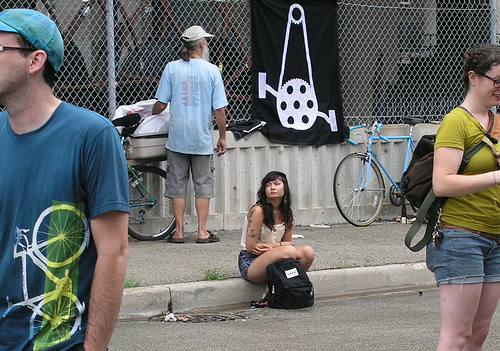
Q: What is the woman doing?
A: Sitting.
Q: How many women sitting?
A: One.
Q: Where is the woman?
A: By the sidewalk.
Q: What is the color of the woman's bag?
A: Black.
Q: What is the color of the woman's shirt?
A: White.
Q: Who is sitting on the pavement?
A: A woman.